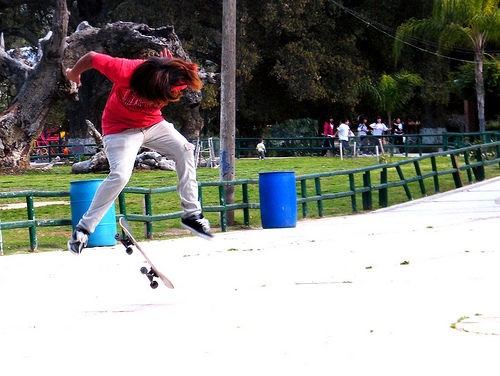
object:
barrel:
[258, 171, 297, 228]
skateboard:
[120, 218, 175, 298]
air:
[141, 185, 175, 230]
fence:
[0, 131, 500, 257]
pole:
[220, 0, 237, 225]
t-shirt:
[90, 51, 197, 137]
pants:
[73, 119, 203, 234]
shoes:
[67, 227, 91, 257]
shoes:
[180, 214, 215, 241]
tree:
[391, 0, 500, 152]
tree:
[2, 5, 78, 174]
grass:
[0, 154, 499, 255]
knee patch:
[182, 140, 195, 158]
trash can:
[69, 179, 118, 247]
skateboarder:
[64, 47, 215, 256]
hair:
[128, 55, 205, 109]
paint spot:
[219, 150, 235, 178]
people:
[388, 116, 406, 156]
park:
[0, 0, 499, 256]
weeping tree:
[346, 68, 425, 144]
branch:
[71, 119, 175, 175]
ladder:
[193, 136, 217, 170]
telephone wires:
[347, 11, 500, 65]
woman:
[319, 116, 339, 157]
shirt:
[324, 122, 335, 139]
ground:
[0, 150, 499, 376]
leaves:
[278, 68, 290, 77]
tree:
[255, 6, 373, 120]